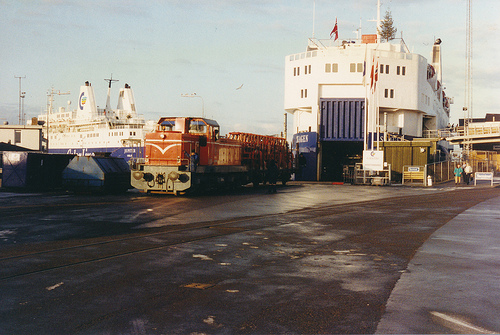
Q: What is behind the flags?
A: A ship.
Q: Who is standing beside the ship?
A: Workers.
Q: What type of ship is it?
A: A cruise ship.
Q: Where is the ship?
A: At the port.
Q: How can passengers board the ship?
A: Using the ramp.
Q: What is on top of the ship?
A: A flag.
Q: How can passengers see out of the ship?
A: Using the windows.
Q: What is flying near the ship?
A: A bird.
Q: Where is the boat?
A: In water.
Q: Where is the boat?
A: In distance.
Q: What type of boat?
A: Carnival.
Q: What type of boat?
A: Cruise.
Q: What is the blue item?
A: Door.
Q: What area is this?
A: Shipping yard.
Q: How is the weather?
A: Fair.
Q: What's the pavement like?
A: Wet.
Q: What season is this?
A: Summer.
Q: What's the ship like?
A: Rusty.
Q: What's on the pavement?
A: Paint.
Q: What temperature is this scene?
A: Cool.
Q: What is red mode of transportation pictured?
A: A train.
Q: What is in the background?
A: Ship.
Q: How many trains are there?
A: 1.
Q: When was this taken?
A: Daytime.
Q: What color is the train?
A: Red.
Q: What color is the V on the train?
A: White.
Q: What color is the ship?
A: White.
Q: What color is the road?
A: Black.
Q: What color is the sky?
A: Light grey.